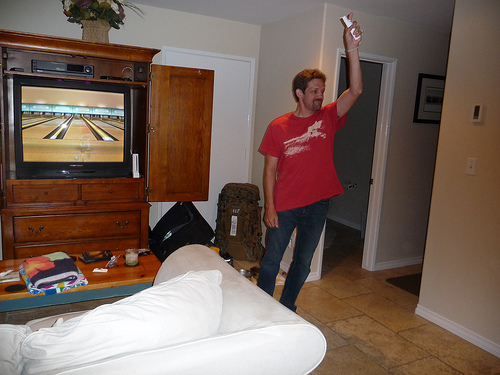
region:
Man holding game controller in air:
[258, 11, 365, 311]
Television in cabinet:
[9, 78, 139, 178]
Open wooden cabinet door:
[143, 62, 217, 200]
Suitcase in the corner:
[216, 181, 260, 259]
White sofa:
[0, 243, 327, 373]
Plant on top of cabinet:
[57, 0, 143, 43]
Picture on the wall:
[411, 72, 453, 127]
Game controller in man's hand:
[339, 11, 368, 43]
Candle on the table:
[124, 245, 142, 267]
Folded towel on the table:
[19, 249, 81, 292]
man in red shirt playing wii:
[261, 30, 379, 297]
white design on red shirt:
[270, 112, 348, 179]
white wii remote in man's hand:
[334, 10, 364, 48]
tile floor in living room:
[306, 257, 448, 366]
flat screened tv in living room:
[12, 70, 149, 181]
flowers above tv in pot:
[69, 9, 131, 62]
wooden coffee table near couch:
[2, 233, 169, 318]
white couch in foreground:
[0, 233, 302, 368]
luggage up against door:
[202, 153, 266, 244]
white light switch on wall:
[453, 145, 478, 176]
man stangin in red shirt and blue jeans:
[255, 5, 384, 326]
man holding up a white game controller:
[269, 11, 374, 210]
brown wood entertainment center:
[3, 26, 218, 250]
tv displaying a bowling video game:
[8, 79, 139, 191]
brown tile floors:
[281, 270, 498, 373]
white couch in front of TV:
[0, 237, 342, 369]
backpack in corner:
[213, 169, 269, 266]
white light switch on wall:
[458, 148, 485, 185]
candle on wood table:
[113, 238, 154, 284]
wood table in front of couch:
[5, 243, 307, 369]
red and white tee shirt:
[261, 104, 346, 211]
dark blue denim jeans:
[260, 197, 331, 313]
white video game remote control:
[342, 14, 361, 43]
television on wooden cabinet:
[6, 80, 140, 175]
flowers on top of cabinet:
[65, 1, 126, 41]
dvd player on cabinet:
[30, 58, 96, 79]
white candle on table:
[126, 249, 138, 266]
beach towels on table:
[16, 251, 88, 295]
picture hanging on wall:
[416, 71, 444, 127]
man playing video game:
[259, 15, 363, 307]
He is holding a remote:
[326, 7, 374, 47]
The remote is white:
[333, 7, 371, 49]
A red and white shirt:
[250, 100, 375, 222]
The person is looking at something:
[270, 60, 337, 117]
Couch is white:
[3, 235, 328, 373]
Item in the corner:
[217, 174, 276, 271]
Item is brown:
[214, 172, 264, 264]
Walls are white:
[173, 14, 307, 53]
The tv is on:
[13, 75, 139, 179]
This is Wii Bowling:
[21, 87, 126, 165]